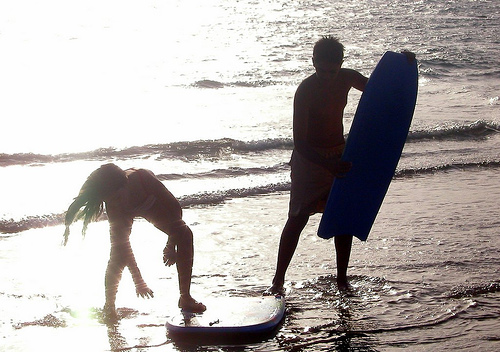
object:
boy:
[260, 34, 371, 305]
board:
[313, 47, 421, 247]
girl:
[58, 158, 214, 327]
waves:
[0, 113, 497, 240]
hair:
[60, 160, 130, 247]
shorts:
[281, 137, 344, 223]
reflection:
[7, 2, 279, 142]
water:
[16, 2, 496, 233]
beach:
[13, 264, 499, 349]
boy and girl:
[54, 33, 383, 327]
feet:
[269, 275, 363, 304]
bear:
[51, 17, 108, 68]